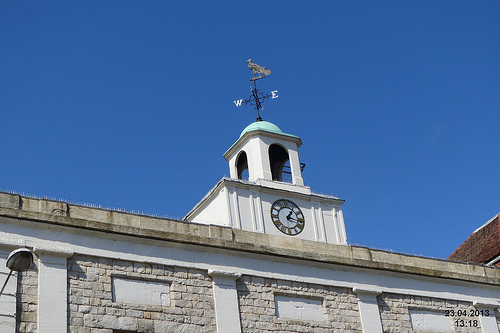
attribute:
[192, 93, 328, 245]
top — white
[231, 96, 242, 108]
w — bronze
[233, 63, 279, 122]
weather vane — bronze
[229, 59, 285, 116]
vane — bronze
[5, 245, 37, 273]
light — off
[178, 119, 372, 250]
tower — white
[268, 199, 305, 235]
clock — brown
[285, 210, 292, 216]
hands — black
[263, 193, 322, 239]
face — white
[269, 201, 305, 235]
numbers — black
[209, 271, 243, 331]
pillar — white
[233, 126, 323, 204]
window — open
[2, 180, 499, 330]
building — white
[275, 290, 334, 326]
square — white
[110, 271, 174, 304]
square — white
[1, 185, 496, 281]
ledge — tan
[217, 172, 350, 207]
ledge — tan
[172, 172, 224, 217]
ledge — tan